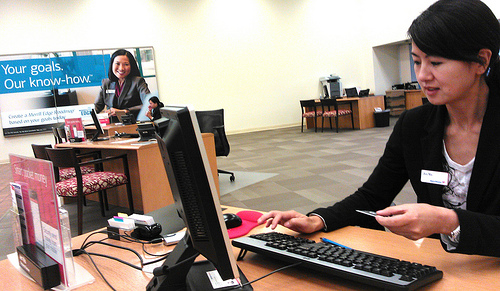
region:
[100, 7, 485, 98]
Two young Asian women working at their desk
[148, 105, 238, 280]
Flat screen computer monitor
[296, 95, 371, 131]
Empty desk and chairs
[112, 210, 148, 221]
Tray of business cards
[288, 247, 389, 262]
Black computer keyboard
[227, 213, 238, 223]
Black computer mouse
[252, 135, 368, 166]
Tan carpeted floor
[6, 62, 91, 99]
Large sign with blue graphic and white lettering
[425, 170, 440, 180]
Company name tag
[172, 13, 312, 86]
Large white wall.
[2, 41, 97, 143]
a sign hanging on a wall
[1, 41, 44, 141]
a wall hanging a sign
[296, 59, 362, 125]
an empty desk sitting in the back of the room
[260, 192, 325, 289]
a woman typing on a keyboard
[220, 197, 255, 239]
a red mousepad sitting under a mouse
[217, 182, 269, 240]
a red mousepad sitting on a desk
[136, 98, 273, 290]
computer monitor sitting on a desk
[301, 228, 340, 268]
a blue pen sitting near a keyboard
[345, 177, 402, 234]
a woman holding a card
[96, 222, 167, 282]
cords attatched to a computer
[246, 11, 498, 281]
lady holding credit card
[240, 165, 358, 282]
lady typing on key board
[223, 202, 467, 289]
keyboard on table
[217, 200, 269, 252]
black mouse on table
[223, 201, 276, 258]
red mouse pad on table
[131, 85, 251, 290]
computer screen on table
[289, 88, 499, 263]
lady wearing black jacket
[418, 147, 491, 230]
lady wearing black and white top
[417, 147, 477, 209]
lady wearing a badge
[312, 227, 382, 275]
blue pen on table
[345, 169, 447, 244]
A card is in a person's hand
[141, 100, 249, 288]
Desktop monitor on a desk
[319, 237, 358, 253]
Blue pen on a desk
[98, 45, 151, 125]
Woman smiling in the background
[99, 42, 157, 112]
Woman has brunette hair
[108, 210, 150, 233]
Business cards on a desk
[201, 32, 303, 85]
White wall in a office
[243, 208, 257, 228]
Red mouse pad on a desk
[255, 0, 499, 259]
a woman wearing a business jacket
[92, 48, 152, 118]
an image of a woman on a poster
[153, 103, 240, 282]
a flatscreen computer monitor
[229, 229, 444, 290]
a computer keyboard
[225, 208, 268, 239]
a pink mousepad with ergonomic wrist support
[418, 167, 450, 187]
a nametag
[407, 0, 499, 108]
the face of a woman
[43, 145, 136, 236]
a chair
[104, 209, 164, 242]
business card holders with business cards in them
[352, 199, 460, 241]
a hand holding a bank card